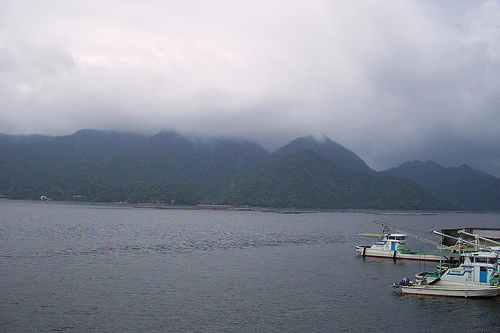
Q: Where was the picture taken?
A: It was taken at the sea.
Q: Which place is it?
A: It is a sea.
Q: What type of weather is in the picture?
A: It is foggy.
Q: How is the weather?
A: It is foggy.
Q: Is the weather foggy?
A: Yes, it is foggy.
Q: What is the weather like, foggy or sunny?
A: It is foggy.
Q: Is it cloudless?
A: No, it is foggy.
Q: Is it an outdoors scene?
A: Yes, it is outdoors.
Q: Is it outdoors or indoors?
A: It is outdoors.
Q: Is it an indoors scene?
A: No, it is outdoors.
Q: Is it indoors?
A: No, it is outdoors.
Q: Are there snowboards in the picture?
A: No, there are no snowboards.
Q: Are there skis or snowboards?
A: No, there are no snowboards or skis.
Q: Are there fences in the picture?
A: No, there are no fences.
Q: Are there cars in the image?
A: No, there are no cars.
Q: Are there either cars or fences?
A: No, there are no cars or fences.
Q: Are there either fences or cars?
A: No, there are no cars or fences.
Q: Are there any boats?
A: Yes, there is a boat.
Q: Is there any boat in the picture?
A: Yes, there is a boat.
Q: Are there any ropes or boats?
A: Yes, there is a boat.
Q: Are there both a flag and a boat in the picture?
A: No, there is a boat but no flags.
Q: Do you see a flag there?
A: No, there are no flags.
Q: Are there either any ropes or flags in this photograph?
A: No, there are no flags or ropes.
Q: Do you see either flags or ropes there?
A: No, there are no flags or ropes.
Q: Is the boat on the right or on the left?
A: The boat is on the right of the image.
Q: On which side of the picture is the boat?
A: The boat is on the right of the image.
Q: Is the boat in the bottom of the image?
A: Yes, the boat is in the bottom of the image.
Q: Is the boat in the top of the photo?
A: No, the boat is in the bottom of the image.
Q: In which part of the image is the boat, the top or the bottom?
A: The boat is in the bottom of the image.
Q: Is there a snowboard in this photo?
A: No, there are no snowboards.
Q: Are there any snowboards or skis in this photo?
A: No, there are no snowboards or skis.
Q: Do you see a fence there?
A: No, there are no fences.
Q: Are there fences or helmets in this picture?
A: No, there are no fences or helmets.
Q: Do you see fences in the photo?
A: No, there are no fences.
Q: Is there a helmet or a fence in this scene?
A: No, there are no fences or helmets.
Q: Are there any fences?
A: No, there are no fences.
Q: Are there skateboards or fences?
A: No, there are no fences or skateboards.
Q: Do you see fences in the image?
A: No, there are no fences.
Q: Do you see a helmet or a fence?
A: No, there are no fences or helmets.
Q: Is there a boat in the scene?
A: Yes, there is a boat.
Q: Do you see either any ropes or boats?
A: Yes, there is a boat.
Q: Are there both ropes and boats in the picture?
A: No, there is a boat but no ropes.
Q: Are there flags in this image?
A: No, there are no flags.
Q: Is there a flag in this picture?
A: No, there are no flags.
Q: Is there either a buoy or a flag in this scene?
A: No, there are no flags or buoys.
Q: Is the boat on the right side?
A: Yes, the boat is on the right of the image.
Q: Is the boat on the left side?
A: No, the boat is on the right of the image.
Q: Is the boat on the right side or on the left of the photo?
A: The boat is on the right of the image.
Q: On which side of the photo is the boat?
A: The boat is on the right of the image.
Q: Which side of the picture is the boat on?
A: The boat is on the right of the image.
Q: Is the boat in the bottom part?
A: Yes, the boat is in the bottom of the image.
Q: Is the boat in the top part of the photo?
A: No, the boat is in the bottom of the image.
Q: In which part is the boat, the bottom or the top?
A: The boat is in the bottom of the image.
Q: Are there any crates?
A: No, there are no crates.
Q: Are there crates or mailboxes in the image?
A: No, there are no crates or mailboxes.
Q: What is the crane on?
A: The crane is on the boat.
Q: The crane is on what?
A: The crane is on the boat.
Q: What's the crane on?
A: The crane is on the boat.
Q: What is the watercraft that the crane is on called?
A: The watercraft is a boat.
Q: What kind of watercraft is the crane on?
A: The crane is on the boat.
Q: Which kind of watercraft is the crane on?
A: The crane is on the boat.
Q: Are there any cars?
A: No, there are no cars.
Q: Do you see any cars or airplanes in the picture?
A: No, there are no cars or airplanes.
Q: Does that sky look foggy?
A: Yes, the sky is foggy.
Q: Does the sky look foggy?
A: Yes, the sky is foggy.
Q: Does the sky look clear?
A: No, the sky is foggy.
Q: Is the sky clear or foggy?
A: The sky is foggy.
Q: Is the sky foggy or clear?
A: The sky is foggy.